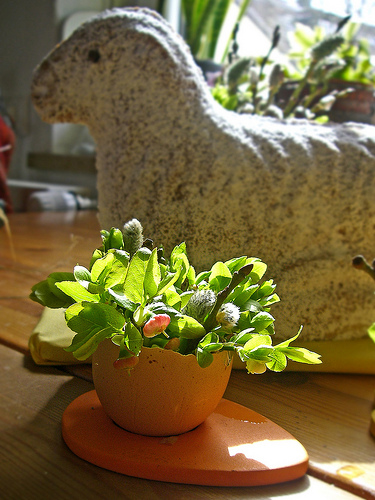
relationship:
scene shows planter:
[4, 6, 374, 498] [90, 335, 231, 437]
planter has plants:
[90, 335, 231, 437] [31, 224, 320, 376]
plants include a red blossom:
[31, 224, 320, 376] [144, 309, 173, 343]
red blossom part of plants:
[144, 309, 173, 343] [31, 224, 320, 376]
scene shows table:
[4, 6, 374, 498] [4, 213, 370, 470]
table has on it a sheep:
[4, 213, 370, 470] [33, 10, 373, 345]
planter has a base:
[90, 335, 231, 437] [61, 391, 310, 480]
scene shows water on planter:
[4, 6, 374, 498] [90, 335, 231, 437]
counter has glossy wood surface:
[5, 220, 92, 372] [23, 221, 78, 257]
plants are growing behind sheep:
[188, 6, 372, 124] [33, 10, 373, 345]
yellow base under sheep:
[31, 303, 371, 372] [33, 10, 373, 345]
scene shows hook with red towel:
[4, 6, 374, 498] [4, 118, 18, 174]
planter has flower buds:
[90, 335, 231, 437] [186, 283, 239, 326]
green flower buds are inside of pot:
[186, 283, 239, 326] [90, 335, 231, 437]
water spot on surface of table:
[334, 458, 361, 485] [4, 213, 370, 470]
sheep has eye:
[33, 10, 373, 345] [88, 46, 104, 65]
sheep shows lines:
[33, 10, 373, 345] [232, 122, 373, 194]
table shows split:
[4, 213, 370, 470] [308, 467, 374, 499]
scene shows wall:
[4, 6, 374, 498] [4, 4, 57, 152]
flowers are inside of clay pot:
[142, 292, 241, 336] [90, 335, 231, 437]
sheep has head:
[33, 10, 373, 345] [31, 12, 213, 134]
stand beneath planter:
[61, 391, 310, 480] [90, 335, 231, 437]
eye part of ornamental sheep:
[88, 46, 104, 65] [33, 10, 373, 345]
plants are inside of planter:
[31, 224, 320, 376] [90, 335, 231, 437]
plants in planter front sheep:
[31, 224, 320, 376] [33, 10, 373, 345]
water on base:
[218, 399, 272, 434] [61, 391, 310, 480]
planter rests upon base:
[90, 335, 231, 437] [61, 391, 310, 480]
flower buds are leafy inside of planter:
[186, 283, 239, 326] [90, 335, 231, 437]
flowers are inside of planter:
[142, 292, 241, 336] [90, 335, 231, 437]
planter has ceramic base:
[90, 335, 231, 437] [61, 391, 310, 480]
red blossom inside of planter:
[144, 309, 173, 343] [90, 335, 231, 437]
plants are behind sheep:
[188, 6, 372, 124] [33, 10, 373, 345]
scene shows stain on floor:
[4, 6, 374, 498] [5, 353, 370, 489]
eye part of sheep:
[88, 46, 104, 65] [33, 10, 373, 345]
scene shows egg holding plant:
[4, 6, 374, 498] [299, 17, 374, 86]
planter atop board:
[90, 335, 231, 437] [2, 348, 357, 497]